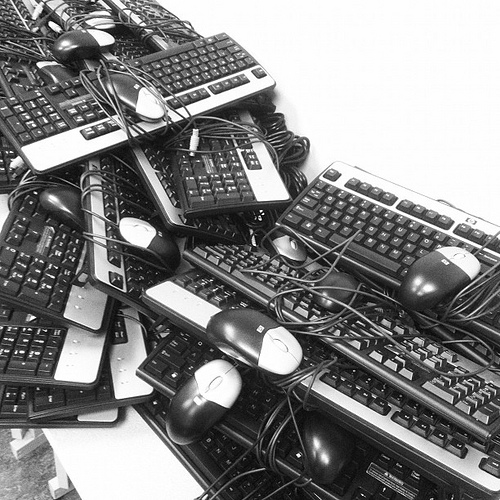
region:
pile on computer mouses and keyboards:
[117, 208, 430, 479]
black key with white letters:
[319, 195, 399, 247]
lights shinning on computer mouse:
[407, 273, 443, 300]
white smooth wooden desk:
[34, 440, 148, 498]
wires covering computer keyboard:
[272, 338, 357, 409]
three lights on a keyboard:
[58, 331, 98, 396]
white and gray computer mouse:
[205, 302, 310, 378]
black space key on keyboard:
[327, 221, 411, 283]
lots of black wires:
[258, 106, 320, 187]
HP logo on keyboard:
[456, 209, 487, 234]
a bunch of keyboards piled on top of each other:
[1, 1, 499, 498]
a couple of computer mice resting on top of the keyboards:
[163, 303, 313, 453]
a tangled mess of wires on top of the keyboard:
[249, 226, 499, 378]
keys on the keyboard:
[281, 163, 445, 273]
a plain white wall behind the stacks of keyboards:
[163, 0, 499, 227]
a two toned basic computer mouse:
[160, 353, 246, 453]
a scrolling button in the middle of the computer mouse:
[208, 373, 226, 389]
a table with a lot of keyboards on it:
[7, 405, 215, 498]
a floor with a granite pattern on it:
[0, 428, 82, 498]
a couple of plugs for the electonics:
[28, 2, 65, 34]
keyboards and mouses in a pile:
[17, 7, 498, 489]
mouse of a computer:
[402, 229, 482, 306]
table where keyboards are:
[34, 441, 162, 498]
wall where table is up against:
[312, 15, 484, 162]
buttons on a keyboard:
[5, 322, 52, 367]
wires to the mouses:
[197, 455, 287, 495]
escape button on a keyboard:
[319, 164, 344, 183]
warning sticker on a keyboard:
[361, 454, 434, 496]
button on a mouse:
[267, 333, 287, 360]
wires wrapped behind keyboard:
[254, 111, 317, 168]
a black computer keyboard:
[275, 154, 499, 339]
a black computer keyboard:
[183, 237, 499, 442]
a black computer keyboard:
[134, 322, 458, 497]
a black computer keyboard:
[133, 392, 309, 499]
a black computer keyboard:
[172, 103, 292, 218]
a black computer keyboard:
[0, 30, 276, 173]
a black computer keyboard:
[81, 155, 163, 318]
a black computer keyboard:
[0, 161, 117, 335]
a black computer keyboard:
[0, 285, 124, 389]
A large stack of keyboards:
[5, 5, 496, 494]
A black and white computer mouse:
[203, 306, 305, 375]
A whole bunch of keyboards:
[8, 8, 493, 495]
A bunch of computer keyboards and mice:
[6, 7, 491, 494]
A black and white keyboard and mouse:
[1, 33, 282, 166]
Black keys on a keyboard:
[286, 163, 493, 301]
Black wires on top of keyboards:
[243, 227, 498, 376]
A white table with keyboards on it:
[231, 13, 489, 218]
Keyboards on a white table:
[3, 267, 208, 499]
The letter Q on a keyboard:
[322, 193, 337, 205]